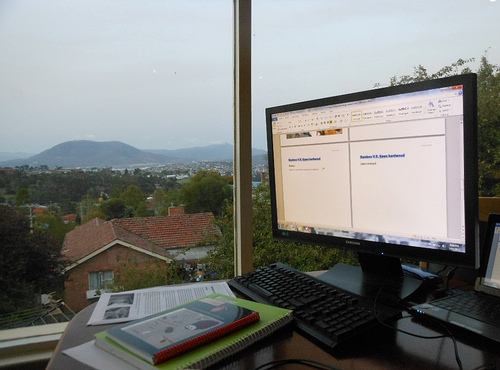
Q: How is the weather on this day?
A: It is cloudy.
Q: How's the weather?
A: It is cloudy.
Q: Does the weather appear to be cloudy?
A: Yes, it is cloudy.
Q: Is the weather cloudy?
A: Yes, it is cloudy.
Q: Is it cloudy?
A: Yes, it is cloudy.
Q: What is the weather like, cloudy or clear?
A: It is cloudy.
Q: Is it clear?
A: No, it is cloudy.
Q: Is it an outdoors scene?
A: Yes, it is outdoors.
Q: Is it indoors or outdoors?
A: It is outdoors.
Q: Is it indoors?
A: No, it is outdoors.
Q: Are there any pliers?
A: No, there are no pliers.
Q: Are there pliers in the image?
A: No, there are no pliers.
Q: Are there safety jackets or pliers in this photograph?
A: No, there are no pliers or safety jackets.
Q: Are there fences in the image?
A: No, there are no fences.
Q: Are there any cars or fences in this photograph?
A: No, there are no fences or cars.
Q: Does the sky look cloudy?
A: Yes, the sky is cloudy.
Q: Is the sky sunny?
A: No, the sky is cloudy.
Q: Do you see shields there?
A: No, there are no shields.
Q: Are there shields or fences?
A: No, there are no shields or fences.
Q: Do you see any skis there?
A: No, there are no skis.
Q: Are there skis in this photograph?
A: No, there are no skis.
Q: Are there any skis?
A: No, there are no skis.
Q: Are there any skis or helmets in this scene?
A: No, there are no skis or helmets.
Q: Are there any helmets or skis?
A: No, there are no skis or helmets.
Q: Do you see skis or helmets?
A: No, there are no skis or helmets.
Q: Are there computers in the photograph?
A: Yes, there is a computer.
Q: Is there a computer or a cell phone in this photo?
A: Yes, there is a computer.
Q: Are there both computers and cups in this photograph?
A: No, there is a computer but no cups.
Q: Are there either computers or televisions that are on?
A: Yes, the computer is on.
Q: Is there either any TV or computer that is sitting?
A: Yes, the computer is sitting.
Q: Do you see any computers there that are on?
A: Yes, there is a computer that is on.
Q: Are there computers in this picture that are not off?
A: Yes, there is a computer that is on.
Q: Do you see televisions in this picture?
A: No, there are no televisions.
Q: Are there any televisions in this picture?
A: No, there are no televisions.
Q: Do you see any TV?
A: No, there are no televisions.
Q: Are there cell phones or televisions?
A: No, there are no televisions or cell phones.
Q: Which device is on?
A: The device is a computer.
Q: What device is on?
A: The device is a computer.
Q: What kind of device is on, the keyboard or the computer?
A: The computer is on.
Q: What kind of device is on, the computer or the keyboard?
A: The computer is on.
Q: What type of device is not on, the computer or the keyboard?
A: The keyboard is not on.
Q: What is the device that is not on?
A: The device is a keyboard.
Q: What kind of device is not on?
A: The device is a keyboard.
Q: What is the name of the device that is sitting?
A: The device is a computer.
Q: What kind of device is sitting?
A: The device is a computer.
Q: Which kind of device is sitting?
A: The device is a computer.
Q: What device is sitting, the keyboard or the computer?
A: The computer is sitting.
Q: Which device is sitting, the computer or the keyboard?
A: The computer is sitting.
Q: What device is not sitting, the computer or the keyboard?
A: The keyboard is not sitting.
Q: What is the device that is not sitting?
A: The device is a keyboard.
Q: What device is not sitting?
A: The device is a keyboard.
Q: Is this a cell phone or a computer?
A: This is a computer.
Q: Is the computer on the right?
A: Yes, the computer is on the right of the image.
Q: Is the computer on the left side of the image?
A: No, the computer is on the right of the image.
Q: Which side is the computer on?
A: The computer is on the right of the image.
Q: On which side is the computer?
A: The computer is on the right of the image.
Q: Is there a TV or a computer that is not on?
A: No, there is a computer but it is on.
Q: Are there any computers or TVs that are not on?
A: No, there is a computer but it is on.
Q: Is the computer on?
A: Yes, the computer is on.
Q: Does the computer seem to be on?
A: Yes, the computer is on.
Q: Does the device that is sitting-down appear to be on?
A: Yes, the computer is on.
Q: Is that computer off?
A: No, the computer is on.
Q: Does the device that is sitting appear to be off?
A: No, the computer is on.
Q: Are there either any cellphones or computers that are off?
A: No, there is a computer but it is on.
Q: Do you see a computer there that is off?
A: No, there is a computer but it is on.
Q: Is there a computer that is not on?
A: No, there is a computer but it is on.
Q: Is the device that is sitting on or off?
A: The computer is on.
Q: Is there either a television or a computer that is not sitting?
A: No, there is a computer but it is sitting.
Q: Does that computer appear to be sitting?
A: Yes, the computer is sitting.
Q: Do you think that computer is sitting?
A: Yes, the computer is sitting.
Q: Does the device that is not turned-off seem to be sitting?
A: Yes, the computer is sitting.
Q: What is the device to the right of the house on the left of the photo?
A: The device is a computer.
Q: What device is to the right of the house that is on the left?
A: The device is a computer.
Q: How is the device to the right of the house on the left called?
A: The device is a computer.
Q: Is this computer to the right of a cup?
A: No, the computer is to the right of the house.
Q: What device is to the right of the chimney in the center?
A: The device is a computer.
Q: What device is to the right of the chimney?
A: The device is a computer.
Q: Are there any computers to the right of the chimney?
A: Yes, there is a computer to the right of the chimney.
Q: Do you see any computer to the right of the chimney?
A: Yes, there is a computer to the right of the chimney.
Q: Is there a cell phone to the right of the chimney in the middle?
A: No, there is a computer to the right of the chimney.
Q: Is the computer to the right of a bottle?
A: No, the computer is to the right of the chimney.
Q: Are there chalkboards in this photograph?
A: No, there are no chalkboards.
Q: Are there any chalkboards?
A: No, there are no chalkboards.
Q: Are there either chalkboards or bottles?
A: No, there are no chalkboards or bottles.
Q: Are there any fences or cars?
A: No, there are no fences or cars.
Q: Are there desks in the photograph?
A: Yes, there is a desk.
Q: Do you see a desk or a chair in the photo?
A: Yes, there is a desk.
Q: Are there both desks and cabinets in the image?
A: No, there is a desk but no cabinets.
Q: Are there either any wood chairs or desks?
A: Yes, there is a wood desk.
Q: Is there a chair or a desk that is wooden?
A: Yes, the desk is wooden.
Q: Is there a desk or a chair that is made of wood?
A: Yes, the desk is made of wood.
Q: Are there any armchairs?
A: No, there are no armchairs.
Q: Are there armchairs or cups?
A: No, there are no armchairs or cups.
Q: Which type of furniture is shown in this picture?
A: The furniture is a desk.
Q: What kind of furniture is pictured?
A: The furniture is a desk.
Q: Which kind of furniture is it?
A: The piece of furniture is a desk.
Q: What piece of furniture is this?
A: This is a desk.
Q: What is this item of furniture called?
A: This is a desk.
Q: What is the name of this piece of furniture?
A: This is a desk.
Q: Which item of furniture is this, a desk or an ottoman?
A: This is a desk.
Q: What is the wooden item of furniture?
A: The piece of furniture is a desk.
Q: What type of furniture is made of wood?
A: The furniture is a desk.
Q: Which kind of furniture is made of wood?
A: The furniture is a desk.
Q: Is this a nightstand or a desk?
A: This is a desk.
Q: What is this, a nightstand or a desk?
A: This is a desk.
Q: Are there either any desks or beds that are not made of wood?
A: No, there is a desk but it is made of wood.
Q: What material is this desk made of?
A: The desk is made of wood.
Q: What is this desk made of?
A: The desk is made of wood.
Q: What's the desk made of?
A: The desk is made of wood.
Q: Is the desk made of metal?
A: No, the desk is made of wood.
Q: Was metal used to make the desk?
A: No, the desk is made of wood.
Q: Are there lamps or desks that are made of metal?
A: No, there is a desk but it is made of wood.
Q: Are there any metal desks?
A: No, there is a desk but it is made of wood.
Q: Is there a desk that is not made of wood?
A: No, there is a desk but it is made of wood.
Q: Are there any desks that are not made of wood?
A: No, there is a desk but it is made of wood.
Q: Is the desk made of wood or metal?
A: The desk is made of wood.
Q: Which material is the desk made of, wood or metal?
A: The desk is made of wood.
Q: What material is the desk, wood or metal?
A: The desk is made of wood.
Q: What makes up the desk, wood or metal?
A: The desk is made of wood.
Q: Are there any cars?
A: No, there are no cars.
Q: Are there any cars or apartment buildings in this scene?
A: No, there are no cars or apartment buildings.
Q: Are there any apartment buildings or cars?
A: No, there are no cars or apartment buildings.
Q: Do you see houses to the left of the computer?
A: Yes, there are houses to the left of the computer.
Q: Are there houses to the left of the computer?
A: Yes, there are houses to the left of the computer.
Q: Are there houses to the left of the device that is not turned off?
A: Yes, there are houses to the left of the computer.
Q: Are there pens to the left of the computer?
A: No, there are houses to the left of the computer.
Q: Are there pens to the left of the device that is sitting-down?
A: No, there are houses to the left of the computer.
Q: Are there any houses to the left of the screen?
A: Yes, there are houses to the left of the screen.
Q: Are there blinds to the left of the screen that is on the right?
A: No, there are houses to the left of the screen.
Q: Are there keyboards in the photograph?
A: Yes, there is a keyboard.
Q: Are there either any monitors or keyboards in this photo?
A: Yes, there is a keyboard.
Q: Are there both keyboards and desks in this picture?
A: Yes, there are both a keyboard and a desk.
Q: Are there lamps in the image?
A: No, there are no lamps.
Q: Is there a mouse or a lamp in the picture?
A: No, there are no lamps or computer mice.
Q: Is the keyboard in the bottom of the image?
A: Yes, the keyboard is in the bottom of the image.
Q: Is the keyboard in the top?
A: No, the keyboard is in the bottom of the image.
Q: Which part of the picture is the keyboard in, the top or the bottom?
A: The keyboard is in the bottom of the image.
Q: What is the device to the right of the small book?
A: The device is a keyboard.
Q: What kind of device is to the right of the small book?
A: The device is a keyboard.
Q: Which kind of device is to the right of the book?
A: The device is a keyboard.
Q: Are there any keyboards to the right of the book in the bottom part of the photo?
A: Yes, there is a keyboard to the right of the book.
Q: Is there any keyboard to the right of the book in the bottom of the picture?
A: Yes, there is a keyboard to the right of the book.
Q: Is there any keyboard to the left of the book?
A: No, the keyboard is to the right of the book.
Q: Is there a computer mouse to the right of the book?
A: No, there is a keyboard to the right of the book.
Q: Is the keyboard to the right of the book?
A: Yes, the keyboard is to the right of the book.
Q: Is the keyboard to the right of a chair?
A: No, the keyboard is to the right of the book.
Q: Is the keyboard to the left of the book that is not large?
A: No, the keyboard is to the right of the book.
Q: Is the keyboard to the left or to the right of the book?
A: The keyboard is to the right of the book.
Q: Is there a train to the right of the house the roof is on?
A: No, there is a keyboard to the right of the house.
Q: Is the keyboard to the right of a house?
A: Yes, the keyboard is to the right of a house.